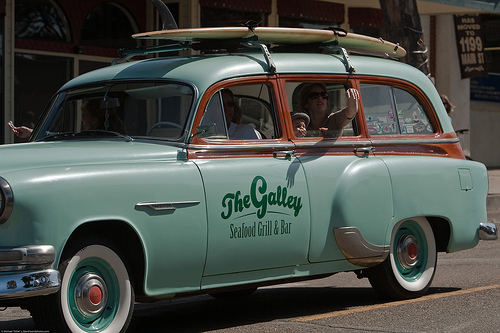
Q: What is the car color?
A: Aqua.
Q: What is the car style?
A: Classic.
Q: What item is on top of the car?
A: Surfboard.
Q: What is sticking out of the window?
A: Hand.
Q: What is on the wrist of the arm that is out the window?
A: Bracelet.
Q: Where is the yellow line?
A: On the road.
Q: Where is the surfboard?
A: On top of the car.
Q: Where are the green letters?
A: On the car door.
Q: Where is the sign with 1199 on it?
A: Behind the car.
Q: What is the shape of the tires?
A: Round.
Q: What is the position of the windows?
A: Down.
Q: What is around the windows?
A: Wood trim.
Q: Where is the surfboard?
A: On the roof.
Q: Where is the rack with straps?
A: On the car.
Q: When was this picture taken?
A: Daytime.